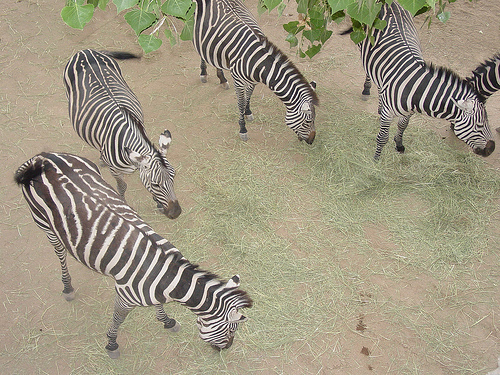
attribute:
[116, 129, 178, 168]
ears — back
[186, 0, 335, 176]
zebra — standing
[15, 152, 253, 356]
zebra — eating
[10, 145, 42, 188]
tail — black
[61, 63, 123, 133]
stripes — black, white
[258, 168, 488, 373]
ground — dirt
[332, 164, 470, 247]
grass — dried, green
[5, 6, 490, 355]
zebras — four, eating, black, white, striped, zebra, grazing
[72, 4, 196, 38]
leaves — green